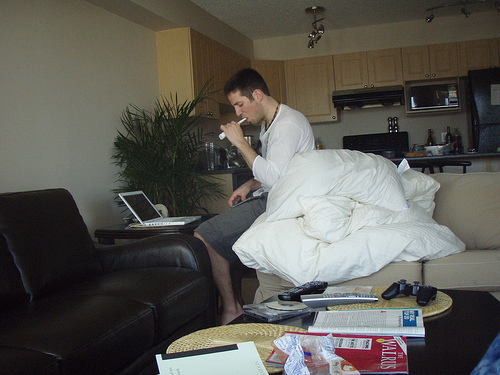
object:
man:
[187, 60, 322, 333]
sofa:
[247, 165, 500, 304]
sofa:
[1, 180, 227, 373]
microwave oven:
[406, 80, 464, 113]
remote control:
[274, 277, 333, 302]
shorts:
[188, 190, 276, 267]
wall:
[2, 2, 171, 253]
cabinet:
[330, 44, 406, 94]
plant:
[110, 75, 231, 230]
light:
[301, 2, 330, 54]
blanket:
[228, 147, 474, 290]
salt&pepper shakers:
[385, 114, 402, 135]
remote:
[377, 273, 440, 307]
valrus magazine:
[256, 326, 415, 375]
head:
[220, 65, 282, 130]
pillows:
[256, 144, 414, 224]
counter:
[374, 146, 499, 174]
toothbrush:
[217, 115, 250, 141]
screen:
[120, 190, 163, 224]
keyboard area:
[146, 215, 202, 225]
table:
[148, 279, 500, 374]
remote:
[295, 291, 386, 311]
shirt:
[253, 101, 321, 201]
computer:
[117, 185, 205, 229]